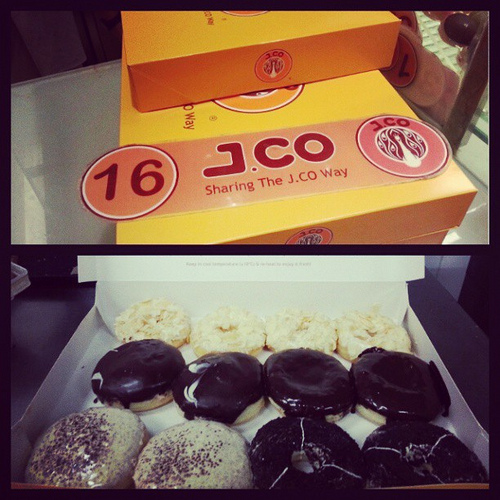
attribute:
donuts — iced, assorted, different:
[26, 301, 478, 489]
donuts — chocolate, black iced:
[97, 343, 472, 482]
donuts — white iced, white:
[116, 298, 416, 359]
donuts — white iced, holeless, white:
[20, 409, 254, 489]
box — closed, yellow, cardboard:
[119, 17, 467, 244]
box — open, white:
[8, 255, 491, 489]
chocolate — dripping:
[180, 353, 263, 420]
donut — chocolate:
[91, 339, 180, 413]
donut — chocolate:
[179, 346, 266, 422]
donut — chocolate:
[265, 347, 356, 420]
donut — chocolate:
[348, 352, 439, 419]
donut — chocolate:
[254, 416, 363, 489]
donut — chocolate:
[364, 421, 487, 487]